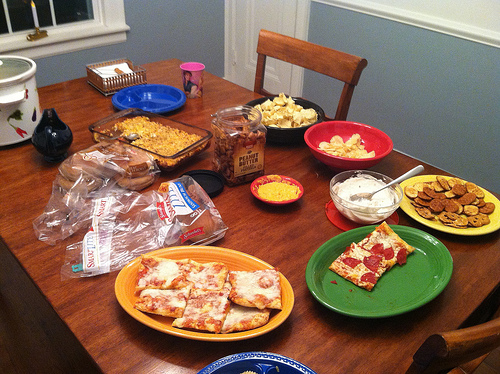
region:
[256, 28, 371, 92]
top of a wooden chair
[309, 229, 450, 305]
a green plate with two square pizza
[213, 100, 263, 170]
an opened plastic container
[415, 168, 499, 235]
a yellow plate with crackers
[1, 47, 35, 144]
a white rice cooker with flower patterns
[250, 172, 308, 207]
a red boal with mustard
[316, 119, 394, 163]
a red bowl with chips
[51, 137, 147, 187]
a plastic bag with hamburger buns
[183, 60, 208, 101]
a pink cup on a wood table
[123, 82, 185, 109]
a blue plate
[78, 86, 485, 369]
There is food on the table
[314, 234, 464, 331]
This plate is green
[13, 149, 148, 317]
The table is wooden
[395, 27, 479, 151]
The wall is blue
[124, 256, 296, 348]
The pizza is piled up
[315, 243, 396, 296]
There is pepperoni on the pizza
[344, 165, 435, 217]
The spoon is silver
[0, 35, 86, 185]
This is a crock pot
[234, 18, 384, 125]
The chair is wooden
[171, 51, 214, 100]
The cup is pink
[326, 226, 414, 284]
The pepperoni pizza on the green plate.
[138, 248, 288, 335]
The pizza on the yellowish orange plate.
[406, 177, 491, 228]
The cookies on the yellow plate.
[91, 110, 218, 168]
The baking pan with food in it on the table.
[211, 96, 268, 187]
The plastic jar next to the baking pan.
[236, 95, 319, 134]
The black bowl on the table.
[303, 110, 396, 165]
The large red bowl on the table.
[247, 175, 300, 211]
The small red bowl on the table.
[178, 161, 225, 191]
The black lid to the plastic jar on the table.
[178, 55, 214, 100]
The pink cup on the table.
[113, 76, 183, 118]
blue plastic plate on the table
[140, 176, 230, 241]
bread rolls in a packet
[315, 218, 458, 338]
plate with two square slices of pizza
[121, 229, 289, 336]
pate with six square slices of pizza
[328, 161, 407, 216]
bowl with a spoon in it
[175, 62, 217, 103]
a plastic cup on the table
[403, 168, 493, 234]
a plate with round crackers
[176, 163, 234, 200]
a screw on lid in front of jar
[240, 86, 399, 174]
two bowls of crisps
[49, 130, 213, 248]
two plastic bags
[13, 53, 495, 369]
a large wooden table with various food items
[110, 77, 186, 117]
blue plastic plate with compartments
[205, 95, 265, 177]
plastic container with peanut butter filled pretzels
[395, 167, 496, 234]
crackers in a yellow plate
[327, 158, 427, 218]
white substance in clear bowl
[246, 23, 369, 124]
a wooden chair back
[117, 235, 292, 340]
pieces of pizza on an orange plate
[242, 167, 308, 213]
yellow substance in small red bowl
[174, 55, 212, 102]
a small cup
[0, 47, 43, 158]
a crock pot